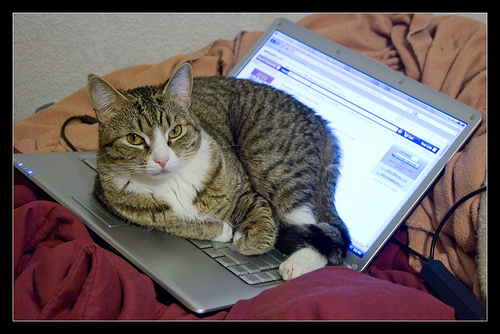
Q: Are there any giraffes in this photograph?
A: No, there are no giraffes.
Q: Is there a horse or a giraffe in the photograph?
A: No, there are no giraffes or horses.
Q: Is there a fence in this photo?
A: No, there are no fences.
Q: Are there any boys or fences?
A: No, there are no fences or boys.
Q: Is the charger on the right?
A: Yes, the charger is on the right of the image.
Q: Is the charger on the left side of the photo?
A: No, the charger is on the right of the image.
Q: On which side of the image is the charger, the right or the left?
A: The charger is on the right of the image.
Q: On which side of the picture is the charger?
A: The charger is on the right of the image.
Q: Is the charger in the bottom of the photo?
A: Yes, the charger is in the bottom of the image.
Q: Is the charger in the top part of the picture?
A: No, the charger is in the bottom of the image.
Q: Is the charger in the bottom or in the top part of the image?
A: The charger is in the bottom of the image.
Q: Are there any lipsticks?
A: No, there are no lipsticks.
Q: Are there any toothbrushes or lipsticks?
A: No, there are no lipsticks or toothbrushes.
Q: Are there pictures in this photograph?
A: No, there are no pictures.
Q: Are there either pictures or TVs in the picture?
A: No, there are no pictures or tvs.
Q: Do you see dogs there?
A: No, there are no dogs.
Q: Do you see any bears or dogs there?
A: No, there are no dogs or bears.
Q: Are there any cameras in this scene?
A: No, there are no cameras.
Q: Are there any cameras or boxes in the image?
A: No, there are no cameras or boxes.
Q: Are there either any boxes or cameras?
A: No, there are no cameras or boxes.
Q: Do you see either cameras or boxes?
A: No, there are no cameras or boxes.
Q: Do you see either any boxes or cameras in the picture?
A: No, there are no cameras or boxes.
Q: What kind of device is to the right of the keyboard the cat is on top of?
A: The device is a screen.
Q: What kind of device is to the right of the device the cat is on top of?
A: The device is a screen.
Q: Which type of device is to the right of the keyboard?
A: The device is a screen.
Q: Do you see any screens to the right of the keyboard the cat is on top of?
A: Yes, there is a screen to the right of the keyboard.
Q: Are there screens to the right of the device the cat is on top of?
A: Yes, there is a screen to the right of the keyboard.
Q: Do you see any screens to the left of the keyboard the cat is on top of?
A: No, the screen is to the right of the keyboard.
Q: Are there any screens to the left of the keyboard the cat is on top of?
A: No, the screen is to the right of the keyboard.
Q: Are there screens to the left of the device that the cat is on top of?
A: No, the screen is to the right of the keyboard.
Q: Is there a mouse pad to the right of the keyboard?
A: No, there is a screen to the right of the keyboard.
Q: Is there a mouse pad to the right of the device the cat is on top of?
A: No, there is a screen to the right of the keyboard.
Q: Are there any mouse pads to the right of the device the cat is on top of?
A: No, there is a screen to the right of the keyboard.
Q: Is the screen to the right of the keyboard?
A: Yes, the screen is to the right of the keyboard.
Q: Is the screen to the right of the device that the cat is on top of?
A: Yes, the screen is to the right of the keyboard.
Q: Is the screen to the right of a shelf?
A: No, the screen is to the right of the keyboard.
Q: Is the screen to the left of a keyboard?
A: No, the screen is to the right of a keyboard.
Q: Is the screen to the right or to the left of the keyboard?
A: The screen is to the right of the keyboard.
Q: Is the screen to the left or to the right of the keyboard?
A: The screen is to the right of the keyboard.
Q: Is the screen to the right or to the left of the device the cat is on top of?
A: The screen is to the right of the keyboard.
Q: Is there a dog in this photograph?
A: No, there are no dogs.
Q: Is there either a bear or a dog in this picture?
A: No, there are no dogs or bears.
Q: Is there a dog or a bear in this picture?
A: No, there are no dogs or bears.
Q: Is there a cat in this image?
A: Yes, there is a cat.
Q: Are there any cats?
A: Yes, there is a cat.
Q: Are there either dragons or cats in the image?
A: Yes, there is a cat.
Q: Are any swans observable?
A: No, there are no swans.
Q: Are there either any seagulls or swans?
A: No, there are no swans or seagulls.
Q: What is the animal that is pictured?
A: The animal is a cat.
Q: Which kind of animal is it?
A: The animal is a cat.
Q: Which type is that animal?
A: This is a cat.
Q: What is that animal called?
A: This is a cat.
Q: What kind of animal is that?
A: This is a cat.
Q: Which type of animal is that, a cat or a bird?
A: This is a cat.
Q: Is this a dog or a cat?
A: This is a cat.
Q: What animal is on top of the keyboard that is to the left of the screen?
A: The cat is on top of the keyboard.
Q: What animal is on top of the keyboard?
A: The cat is on top of the keyboard.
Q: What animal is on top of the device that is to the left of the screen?
A: The animal is a cat.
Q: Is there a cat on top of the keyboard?
A: Yes, there is a cat on top of the keyboard.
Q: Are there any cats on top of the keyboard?
A: Yes, there is a cat on top of the keyboard.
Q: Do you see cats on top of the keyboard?
A: Yes, there is a cat on top of the keyboard.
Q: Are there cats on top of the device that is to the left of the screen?
A: Yes, there is a cat on top of the keyboard.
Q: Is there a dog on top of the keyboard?
A: No, there is a cat on top of the keyboard.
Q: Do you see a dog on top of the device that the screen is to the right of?
A: No, there is a cat on top of the keyboard.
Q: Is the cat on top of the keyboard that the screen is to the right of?
A: Yes, the cat is on top of the keyboard.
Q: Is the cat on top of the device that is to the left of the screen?
A: Yes, the cat is on top of the keyboard.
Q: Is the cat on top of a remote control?
A: No, the cat is on top of the keyboard.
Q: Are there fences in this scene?
A: No, there are no fences.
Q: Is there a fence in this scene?
A: No, there are no fences.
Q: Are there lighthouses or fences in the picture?
A: No, there are no fences or lighthouses.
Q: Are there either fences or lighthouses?
A: No, there are no fences or lighthouses.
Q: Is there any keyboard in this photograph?
A: Yes, there is a keyboard.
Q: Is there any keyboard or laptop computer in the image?
A: Yes, there is a keyboard.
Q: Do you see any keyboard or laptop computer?
A: Yes, there is a keyboard.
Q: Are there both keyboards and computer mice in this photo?
A: No, there is a keyboard but no computer mice.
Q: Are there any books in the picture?
A: No, there are no books.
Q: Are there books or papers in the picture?
A: No, there are no books or papers.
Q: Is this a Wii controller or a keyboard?
A: This is a keyboard.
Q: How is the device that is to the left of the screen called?
A: The device is a keyboard.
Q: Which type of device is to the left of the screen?
A: The device is a keyboard.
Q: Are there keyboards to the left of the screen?
A: Yes, there is a keyboard to the left of the screen.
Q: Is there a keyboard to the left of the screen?
A: Yes, there is a keyboard to the left of the screen.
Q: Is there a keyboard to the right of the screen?
A: No, the keyboard is to the left of the screen.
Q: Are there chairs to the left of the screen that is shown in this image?
A: No, there is a keyboard to the left of the screen.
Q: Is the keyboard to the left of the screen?
A: Yes, the keyboard is to the left of the screen.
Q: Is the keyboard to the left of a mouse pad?
A: No, the keyboard is to the left of the screen.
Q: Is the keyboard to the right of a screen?
A: No, the keyboard is to the left of a screen.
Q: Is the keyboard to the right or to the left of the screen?
A: The keyboard is to the left of the screen.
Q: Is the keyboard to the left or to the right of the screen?
A: The keyboard is to the left of the screen.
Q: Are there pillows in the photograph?
A: No, there are no pillows.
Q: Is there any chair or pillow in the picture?
A: No, there are no pillows or chairs.